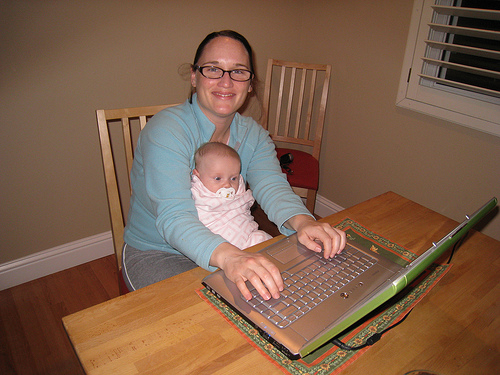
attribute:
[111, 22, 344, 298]
woman — working, typing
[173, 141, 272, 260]
baby — bundled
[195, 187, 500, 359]
laptop — sitting, green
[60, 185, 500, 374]
table — wooden, light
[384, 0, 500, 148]
window — louvered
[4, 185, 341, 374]
flooring — hardwood, cherry colored, wooden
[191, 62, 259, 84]
glasses — oval, brown, round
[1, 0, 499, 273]
wall — taupe, tan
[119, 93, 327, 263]
shirt — blue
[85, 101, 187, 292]
chair — wooden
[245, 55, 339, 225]
chair — wooden, empty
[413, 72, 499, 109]
blind — wooden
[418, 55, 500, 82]
blind — wooden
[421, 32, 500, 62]
blind — wooden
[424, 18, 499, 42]
blind — wooden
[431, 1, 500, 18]
blind — wooden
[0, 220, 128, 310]
baseboard — wooden, white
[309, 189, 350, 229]
baseboard — wooden, white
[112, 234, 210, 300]
pants — gray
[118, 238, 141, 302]
line — blue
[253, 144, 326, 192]
seat — red